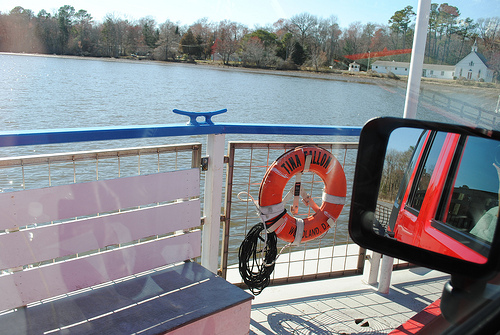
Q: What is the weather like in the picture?
A: It is clear.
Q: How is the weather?
A: It is clear.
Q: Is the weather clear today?
A: Yes, it is clear.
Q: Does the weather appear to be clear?
A: Yes, it is clear.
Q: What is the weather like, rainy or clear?
A: It is clear.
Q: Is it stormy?
A: No, it is clear.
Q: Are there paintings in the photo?
A: No, there are no paintings.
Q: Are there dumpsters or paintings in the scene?
A: No, there are no paintings or dumpsters.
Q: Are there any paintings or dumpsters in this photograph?
A: No, there are no paintings or dumpsters.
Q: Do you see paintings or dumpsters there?
A: No, there are no paintings or dumpsters.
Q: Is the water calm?
A: Yes, the water is calm.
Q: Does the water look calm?
A: Yes, the water is calm.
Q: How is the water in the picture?
A: The water is calm.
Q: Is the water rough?
A: No, the water is calm.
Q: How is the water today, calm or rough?
A: The water is calm.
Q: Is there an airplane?
A: No, there are no airplanes.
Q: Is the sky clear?
A: Yes, the sky is clear.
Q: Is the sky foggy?
A: No, the sky is clear.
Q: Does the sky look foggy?
A: No, the sky is clear.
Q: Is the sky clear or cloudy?
A: The sky is clear.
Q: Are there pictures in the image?
A: No, there are no pictures.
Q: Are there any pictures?
A: No, there are no pictures.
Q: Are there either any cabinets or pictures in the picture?
A: No, there are no pictures or cabinets.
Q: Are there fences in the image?
A: Yes, there is a fence.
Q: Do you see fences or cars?
A: Yes, there is a fence.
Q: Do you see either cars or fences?
A: Yes, there is a fence.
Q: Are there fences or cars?
A: Yes, there is a fence.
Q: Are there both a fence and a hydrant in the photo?
A: No, there is a fence but no fire hydrants.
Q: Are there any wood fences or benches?
A: Yes, there is a wood fence.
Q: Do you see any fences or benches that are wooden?
A: Yes, the fence is wooden.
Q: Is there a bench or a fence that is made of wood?
A: Yes, the fence is made of wood.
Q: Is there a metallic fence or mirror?
A: Yes, there is a metal fence.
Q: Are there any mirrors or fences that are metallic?
A: Yes, the fence is metallic.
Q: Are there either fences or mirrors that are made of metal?
A: Yes, the fence is made of metal.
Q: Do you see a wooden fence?
A: Yes, there is a wood fence.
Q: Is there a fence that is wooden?
A: Yes, there is a fence that is wooden.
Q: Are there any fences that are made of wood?
A: Yes, there is a fence that is made of wood.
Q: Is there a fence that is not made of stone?
A: Yes, there is a fence that is made of wood.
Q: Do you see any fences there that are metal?
A: Yes, there is a metal fence.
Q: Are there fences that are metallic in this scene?
A: Yes, there is a metal fence.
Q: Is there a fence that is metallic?
A: Yes, there is a fence that is metallic.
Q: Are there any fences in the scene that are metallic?
A: Yes, there is a fence that is metallic.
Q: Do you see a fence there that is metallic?
A: Yes, there is a fence that is metallic.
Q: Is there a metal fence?
A: Yes, there is a fence that is made of metal.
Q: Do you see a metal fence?
A: Yes, there is a fence that is made of metal.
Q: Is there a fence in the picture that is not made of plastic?
A: Yes, there is a fence that is made of metal.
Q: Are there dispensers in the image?
A: No, there are no dispensers.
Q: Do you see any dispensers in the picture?
A: No, there are no dispensers.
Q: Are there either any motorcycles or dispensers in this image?
A: No, there are no dispensers or motorcycles.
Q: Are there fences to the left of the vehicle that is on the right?
A: Yes, there is a fence to the left of the car.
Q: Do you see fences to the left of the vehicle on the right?
A: Yes, there is a fence to the left of the car.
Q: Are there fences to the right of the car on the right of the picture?
A: No, the fence is to the left of the car.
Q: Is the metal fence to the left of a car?
A: Yes, the fence is to the left of a car.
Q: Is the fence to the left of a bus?
A: No, the fence is to the left of a car.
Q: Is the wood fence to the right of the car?
A: No, the fence is to the left of the car.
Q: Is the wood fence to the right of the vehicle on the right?
A: No, the fence is to the left of the car.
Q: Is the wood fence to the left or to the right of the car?
A: The fence is to the left of the car.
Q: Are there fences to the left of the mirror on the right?
A: Yes, there is a fence to the left of the mirror.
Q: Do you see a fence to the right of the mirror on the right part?
A: No, the fence is to the left of the mirror.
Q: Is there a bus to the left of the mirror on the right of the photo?
A: No, there is a fence to the left of the mirror.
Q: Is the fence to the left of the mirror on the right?
A: Yes, the fence is to the left of the mirror.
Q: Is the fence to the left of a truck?
A: No, the fence is to the left of the mirror.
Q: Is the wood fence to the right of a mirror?
A: No, the fence is to the left of a mirror.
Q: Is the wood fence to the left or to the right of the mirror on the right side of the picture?
A: The fence is to the left of the mirror.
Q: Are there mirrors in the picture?
A: Yes, there is a mirror.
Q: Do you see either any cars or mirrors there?
A: Yes, there is a mirror.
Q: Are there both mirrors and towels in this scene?
A: No, there is a mirror but no towels.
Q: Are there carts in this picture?
A: No, there are no carts.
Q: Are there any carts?
A: No, there are no carts.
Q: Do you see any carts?
A: No, there are no carts.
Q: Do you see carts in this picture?
A: No, there are no carts.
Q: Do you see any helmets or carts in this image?
A: No, there are no carts or helmets.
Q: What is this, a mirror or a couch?
A: This is a mirror.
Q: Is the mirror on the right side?
A: Yes, the mirror is on the right of the image.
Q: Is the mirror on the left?
A: No, the mirror is on the right of the image.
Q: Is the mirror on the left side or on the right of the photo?
A: The mirror is on the right of the image.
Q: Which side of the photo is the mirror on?
A: The mirror is on the right of the image.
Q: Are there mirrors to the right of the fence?
A: Yes, there is a mirror to the right of the fence.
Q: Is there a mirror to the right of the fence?
A: Yes, there is a mirror to the right of the fence.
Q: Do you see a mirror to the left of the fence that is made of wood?
A: No, the mirror is to the right of the fence.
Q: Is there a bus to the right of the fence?
A: No, there is a mirror to the right of the fence.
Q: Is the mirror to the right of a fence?
A: Yes, the mirror is to the right of a fence.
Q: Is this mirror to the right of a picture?
A: No, the mirror is to the right of a fence.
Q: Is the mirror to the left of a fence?
A: No, the mirror is to the right of a fence.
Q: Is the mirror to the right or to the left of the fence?
A: The mirror is to the right of the fence.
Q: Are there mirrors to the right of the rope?
A: Yes, there is a mirror to the right of the rope.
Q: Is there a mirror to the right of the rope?
A: Yes, there is a mirror to the right of the rope.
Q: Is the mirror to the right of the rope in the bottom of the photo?
A: Yes, the mirror is to the right of the rope.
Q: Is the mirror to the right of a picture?
A: No, the mirror is to the right of the rope.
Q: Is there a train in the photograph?
A: No, there are no trains.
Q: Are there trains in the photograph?
A: No, there are no trains.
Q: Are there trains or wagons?
A: No, there are no trains or wagons.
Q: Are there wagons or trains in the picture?
A: No, there are no trains or wagons.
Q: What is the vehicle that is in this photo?
A: The vehicle is a car.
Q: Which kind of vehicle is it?
A: The vehicle is a car.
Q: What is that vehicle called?
A: This is a car.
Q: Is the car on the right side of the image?
A: Yes, the car is on the right of the image.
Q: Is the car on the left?
A: No, the car is on the right of the image.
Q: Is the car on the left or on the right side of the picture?
A: The car is on the right of the image.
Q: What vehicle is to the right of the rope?
A: The vehicle is a car.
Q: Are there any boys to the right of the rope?
A: No, there is a car to the right of the rope.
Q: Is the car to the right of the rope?
A: Yes, the car is to the right of the rope.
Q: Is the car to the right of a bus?
A: No, the car is to the right of the rope.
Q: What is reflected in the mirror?
A: The car is reflected in the mirror.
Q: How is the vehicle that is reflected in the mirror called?
A: The vehicle is a car.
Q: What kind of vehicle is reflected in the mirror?
A: The vehicle is a car.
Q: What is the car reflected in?
A: The car is reflected in the mirror.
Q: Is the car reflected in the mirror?
A: Yes, the car is reflected in the mirror.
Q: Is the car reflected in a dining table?
A: No, the car is reflected in the mirror.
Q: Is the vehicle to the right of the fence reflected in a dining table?
A: No, the car is reflected in the mirror.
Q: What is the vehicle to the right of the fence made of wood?
A: The vehicle is a car.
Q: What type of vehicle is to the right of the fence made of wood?
A: The vehicle is a car.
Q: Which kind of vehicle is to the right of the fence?
A: The vehicle is a car.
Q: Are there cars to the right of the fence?
A: Yes, there is a car to the right of the fence.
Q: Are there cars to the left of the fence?
A: No, the car is to the right of the fence.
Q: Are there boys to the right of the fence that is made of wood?
A: No, there is a car to the right of the fence.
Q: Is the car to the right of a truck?
A: No, the car is to the right of the fence.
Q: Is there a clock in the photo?
A: No, there are no clocks.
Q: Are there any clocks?
A: No, there are no clocks.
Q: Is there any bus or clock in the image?
A: No, there are no clocks or buses.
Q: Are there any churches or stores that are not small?
A: No, there is a church but it is small.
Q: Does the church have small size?
A: Yes, the church is small.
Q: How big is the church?
A: The church is small.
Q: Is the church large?
A: No, the church is small.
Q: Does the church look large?
A: No, the church is small.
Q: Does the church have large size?
A: No, the church is small.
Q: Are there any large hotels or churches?
A: No, there is a church but it is small.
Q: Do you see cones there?
A: No, there are no cones.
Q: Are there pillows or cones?
A: No, there are no cones or pillows.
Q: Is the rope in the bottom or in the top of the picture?
A: The rope is in the bottom of the image.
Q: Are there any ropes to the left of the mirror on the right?
A: Yes, there is a rope to the left of the mirror.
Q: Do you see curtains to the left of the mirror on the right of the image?
A: No, there is a rope to the left of the mirror.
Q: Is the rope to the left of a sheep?
A: No, the rope is to the left of the mirror.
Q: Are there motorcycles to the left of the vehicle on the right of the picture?
A: No, there is a rope to the left of the car.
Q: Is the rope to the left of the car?
A: Yes, the rope is to the left of the car.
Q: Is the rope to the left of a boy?
A: No, the rope is to the left of the car.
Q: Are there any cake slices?
A: No, there are no cake slices.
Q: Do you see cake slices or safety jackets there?
A: No, there are no cake slices or safety jackets.